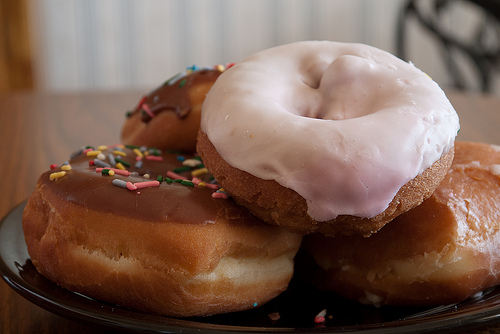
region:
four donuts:
[107, 60, 492, 257]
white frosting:
[218, 103, 353, 177]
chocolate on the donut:
[81, 194, 168, 216]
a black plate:
[83, 292, 158, 329]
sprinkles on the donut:
[108, 162, 170, 196]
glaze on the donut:
[415, 231, 491, 276]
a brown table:
[29, 94, 98, 140]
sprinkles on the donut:
[163, 68, 202, 88]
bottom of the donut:
[133, 276, 230, 307]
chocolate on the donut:
[152, 87, 192, 117]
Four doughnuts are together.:
[1, 39, 495, 328]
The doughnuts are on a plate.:
[0, 30, 496, 331]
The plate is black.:
[0, 187, 496, 327]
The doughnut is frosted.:
[177, 27, 462, 242]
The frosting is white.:
[195, 32, 472, 222]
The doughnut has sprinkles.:
[35, 130, 236, 205]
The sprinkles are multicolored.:
[35, 130, 245, 205]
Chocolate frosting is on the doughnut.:
[30, 135, 255, 235]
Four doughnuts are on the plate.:
[9, 32, 498, 327]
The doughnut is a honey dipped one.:
[298, 140, 496, 311]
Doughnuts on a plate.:
[20, 32, 497, 329]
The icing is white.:
[221, 56, 424, 184]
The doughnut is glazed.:
[409, 155, 498, 275]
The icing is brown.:
[59, 137, 249, 233]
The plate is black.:
[84, 285, 386, 332]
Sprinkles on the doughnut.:
[89, 142, 203, 194]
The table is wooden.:
[1, 101, 81, 171]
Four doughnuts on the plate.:
[29, 46, 496, 332]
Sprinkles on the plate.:
[256, 298, 338, 326]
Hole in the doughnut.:
[277, 60, 375, 142]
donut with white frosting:
[233, 27, 435, 200]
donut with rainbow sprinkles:
[16, 137, 276, 301]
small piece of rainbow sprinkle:
[138, 176, 161, 191]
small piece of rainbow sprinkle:
[114, 178, 133, 190]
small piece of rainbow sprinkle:
[50, 170, 65, 181]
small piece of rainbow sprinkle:
[121, 167, 128, 175]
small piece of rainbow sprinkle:
[212, 188, 227, 199]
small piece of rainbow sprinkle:
[142, 103, 155, 118]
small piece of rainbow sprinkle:
[143, 152, 164, 162]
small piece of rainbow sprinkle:
[91, 147, 106, 159]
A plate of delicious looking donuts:
[37, 54, 499, 312]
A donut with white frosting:
[191, 55, 453, 227]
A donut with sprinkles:
[41, 150, 287, 319]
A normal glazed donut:
[334, 167, 495, 297]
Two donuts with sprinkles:
[50, 62, 271, 292]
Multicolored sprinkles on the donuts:
[57, 139, 219, 192]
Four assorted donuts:
[50, 60, 498, 297]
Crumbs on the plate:
[310, 307, 332, 323]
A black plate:
[331, 295, 478, 332]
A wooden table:
[4, 92, 89, 144]